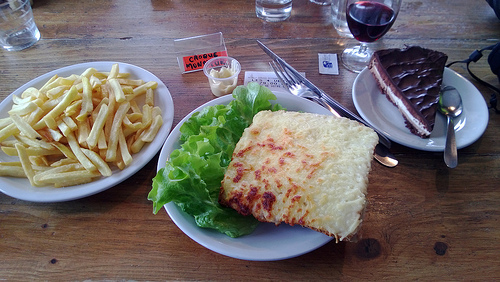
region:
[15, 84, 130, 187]
A plate of testy looking fries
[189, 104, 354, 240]
A plate of testy looking cake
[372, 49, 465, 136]
A plate of testy looking cake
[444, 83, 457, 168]
A shiny silver spoon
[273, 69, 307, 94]
A shiny silver spoon fork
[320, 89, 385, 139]
A shiny silver knife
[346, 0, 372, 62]
A glass of beer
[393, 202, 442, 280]
A wooden table surface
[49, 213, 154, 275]
A wooden table surface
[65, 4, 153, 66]
A wooden table surface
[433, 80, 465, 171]
A spoon resting on a plate.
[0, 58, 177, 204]
A plate of french fries.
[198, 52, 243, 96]
A small container of a condiment.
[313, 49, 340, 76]
A salt package on the table.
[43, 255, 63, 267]
A spot on the table.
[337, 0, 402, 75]
A glass of liquid.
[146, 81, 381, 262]
A plate of food.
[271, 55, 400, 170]
A silver fork on the table.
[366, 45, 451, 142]
A piece of delicious looking pie.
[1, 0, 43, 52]
A cup on the table.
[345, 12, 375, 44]
glass of wine on the table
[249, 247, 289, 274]
white plate with food on it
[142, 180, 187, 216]
lettuce on a white plate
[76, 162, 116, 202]
fries on a white plate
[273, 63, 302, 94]
a fork on the table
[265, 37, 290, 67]
a knife on the table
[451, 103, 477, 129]
a spoon on the white plate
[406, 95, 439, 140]
piece of chocolate cake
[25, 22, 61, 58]
a clear bottle on the table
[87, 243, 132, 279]
a wooden table with food on it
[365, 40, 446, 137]
Chocolate pie on the plate.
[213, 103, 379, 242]
Pizza on the plate.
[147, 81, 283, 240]
Green lettuce on the plate.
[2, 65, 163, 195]
French fries on the plate.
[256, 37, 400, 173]
Metal fork on the table.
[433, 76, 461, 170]
Metal spoon on the table.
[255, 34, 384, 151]
Metal knife on the plate.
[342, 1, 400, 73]
Wine glass on the table.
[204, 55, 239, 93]
White condiment in plastic dish.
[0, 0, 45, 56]
Glass on the table.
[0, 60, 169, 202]
a white late full of French fries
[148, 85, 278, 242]
green salad leaf on a white plate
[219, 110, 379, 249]
a calzone next to some green salad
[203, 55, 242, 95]
a small container of mayonnaise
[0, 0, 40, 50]
an empty glass of water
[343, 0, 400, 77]
a glass of wine on a table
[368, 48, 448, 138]
a slice of chocolate pie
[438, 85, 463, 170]
a spoon on a small white plate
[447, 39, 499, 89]
a black wire on a wooden table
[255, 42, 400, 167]
a fork and knife on a wooden table